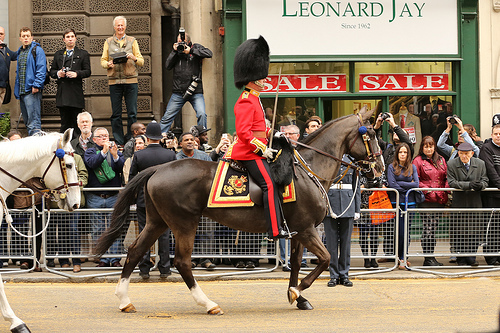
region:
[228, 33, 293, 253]
the man is wearing red and black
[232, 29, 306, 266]
the man has a tall furry hat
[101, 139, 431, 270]
the horse is brown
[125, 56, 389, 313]
the man is riding a brown horse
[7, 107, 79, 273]
the white horse is behind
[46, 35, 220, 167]
people are taking pictures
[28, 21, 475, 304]
they are in the street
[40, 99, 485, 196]
people are watching the horses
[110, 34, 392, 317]
the man and horse are walking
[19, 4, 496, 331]
they are in the city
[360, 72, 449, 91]
red sign with white text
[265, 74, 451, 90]
two red signs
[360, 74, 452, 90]
red Sale sign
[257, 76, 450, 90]
two red signs with white text reading SALE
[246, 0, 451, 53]
white sign with green text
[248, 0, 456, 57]
white sign with green text reading Leonard Jay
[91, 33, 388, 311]
guard on a brown horse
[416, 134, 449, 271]
woman wearing a maroon coat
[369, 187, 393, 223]
orange bag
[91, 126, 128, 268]
older man taking a photo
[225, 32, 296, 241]
An officer riding a horse.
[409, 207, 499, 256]
A metallic barrier.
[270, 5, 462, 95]
A signage in the picture.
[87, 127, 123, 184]
A person holding a camera.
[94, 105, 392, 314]
A brown horse.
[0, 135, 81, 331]
A white horse.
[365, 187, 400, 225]
An orange bag in the picture.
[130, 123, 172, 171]
A police officer with a helmet.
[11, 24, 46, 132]
A man with blue jacket, jeans and checked shirt.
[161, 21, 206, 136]
A man with black jacket and jeans holding taking a picture.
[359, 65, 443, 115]
This sign says SALE in white letters against red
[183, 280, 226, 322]
The hooves of this horse are an off-brown color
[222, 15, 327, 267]
This man is a member of the Royal Guard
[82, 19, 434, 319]
This photo takes place in the city of London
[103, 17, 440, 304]
This photo takes place in the country of the United Kingdom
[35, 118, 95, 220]
The face of this white horse looks sad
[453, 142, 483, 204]
This older man is wearing a grey tweed hat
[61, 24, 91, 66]
This man has a blue tie and is holding a camera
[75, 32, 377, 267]
Jackson Zander took this photo for a travel magazine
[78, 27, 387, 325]
The people in this photo are very excited to see the Royal Guard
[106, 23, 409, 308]
British guard riding horse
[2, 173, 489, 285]
Temporary metal partition fence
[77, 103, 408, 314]
Chestnut brown horse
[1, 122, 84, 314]
White horse with brown reins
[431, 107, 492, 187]
Older woman taking photo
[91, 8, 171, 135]
Smiling man in yellow shirt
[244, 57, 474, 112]
Large red signs reading "SALE"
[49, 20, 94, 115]
Man in black coat holding camera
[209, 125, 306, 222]
Red, gold and black horse saddle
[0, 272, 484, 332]
City street with bits of hay